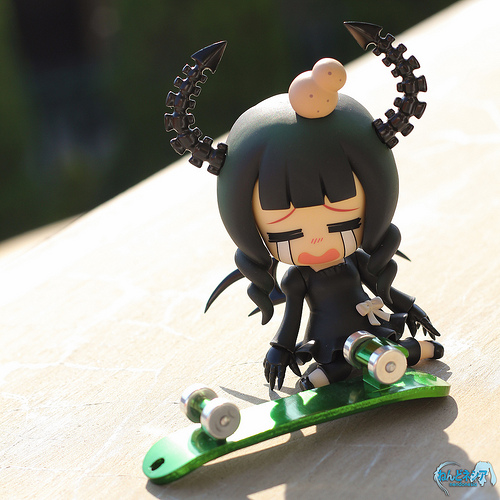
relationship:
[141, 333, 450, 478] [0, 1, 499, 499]
skateboard on a table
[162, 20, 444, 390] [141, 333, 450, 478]
figure near skateboard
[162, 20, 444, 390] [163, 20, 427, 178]
figure with horns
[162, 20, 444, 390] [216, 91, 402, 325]
figure with black hair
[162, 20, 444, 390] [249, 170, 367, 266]
figure with a sad face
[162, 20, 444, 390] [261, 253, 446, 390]
figure in black clothing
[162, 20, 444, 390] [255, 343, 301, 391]
figure with gloves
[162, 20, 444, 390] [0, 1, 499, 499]
figure on a table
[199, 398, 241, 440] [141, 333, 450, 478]
wheel on a skateboard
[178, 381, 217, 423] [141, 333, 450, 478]
wheel on a skateboard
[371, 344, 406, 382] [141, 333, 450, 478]
wheel on a skateboard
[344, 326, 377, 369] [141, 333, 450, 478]
wheel on a skateboard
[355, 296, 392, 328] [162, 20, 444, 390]
bow on figure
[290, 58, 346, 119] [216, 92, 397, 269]
knot on figures head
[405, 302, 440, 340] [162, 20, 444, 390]
hand of figure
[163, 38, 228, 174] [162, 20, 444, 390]
horn of figure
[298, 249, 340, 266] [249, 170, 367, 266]
mouth on face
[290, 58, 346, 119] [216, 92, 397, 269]
knot on top of her head